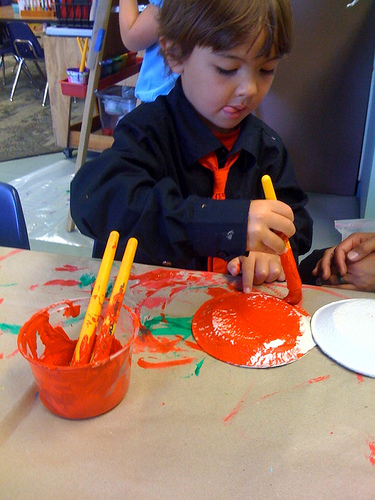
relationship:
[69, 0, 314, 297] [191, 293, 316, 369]
child painting plate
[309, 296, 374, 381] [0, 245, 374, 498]
plate on table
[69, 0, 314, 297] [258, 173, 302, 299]
child holding brush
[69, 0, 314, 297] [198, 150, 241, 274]
child wearing tie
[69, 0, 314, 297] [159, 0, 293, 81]
child has hair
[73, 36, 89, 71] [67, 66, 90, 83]
brush in container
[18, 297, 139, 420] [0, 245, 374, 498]
paint on table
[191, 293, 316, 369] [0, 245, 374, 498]
plate on table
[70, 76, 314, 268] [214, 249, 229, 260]
shirt has button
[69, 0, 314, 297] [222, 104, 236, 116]
child has tongue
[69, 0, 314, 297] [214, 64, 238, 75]
child has eyelashes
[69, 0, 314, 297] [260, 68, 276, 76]
child has eyelashes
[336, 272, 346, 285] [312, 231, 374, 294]
ring on hands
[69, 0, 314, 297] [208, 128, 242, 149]
child wearing shirt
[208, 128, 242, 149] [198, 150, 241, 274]
shirt matches tie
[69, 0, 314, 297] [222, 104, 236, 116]
child sticking out tongue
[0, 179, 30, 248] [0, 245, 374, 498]
chair at table